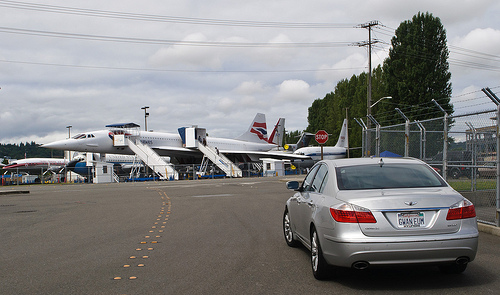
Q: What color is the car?
A: Silver.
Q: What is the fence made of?
A: Metal.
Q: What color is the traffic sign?
A: Red and white.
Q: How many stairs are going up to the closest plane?
A: Two.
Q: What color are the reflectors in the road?
A: Orange.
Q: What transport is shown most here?
A: Airplanes.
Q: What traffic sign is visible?
A: STOP sign.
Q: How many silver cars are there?
A: One.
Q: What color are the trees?
A: Green.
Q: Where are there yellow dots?
A: The road.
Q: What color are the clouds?
A: White.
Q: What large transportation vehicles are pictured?
A: Airplanes.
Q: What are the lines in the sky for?
A: Power lines.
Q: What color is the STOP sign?
A: Red.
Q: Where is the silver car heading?
A: Towards the airport.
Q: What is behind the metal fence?
A: An aircraft.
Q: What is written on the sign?
A: Stop.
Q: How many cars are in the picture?
A: 1.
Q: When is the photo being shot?
A: Daytime.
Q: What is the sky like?
A: Cloudy.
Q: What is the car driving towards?
A: A plane.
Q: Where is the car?
A: On the road.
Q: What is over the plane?
A: Powerlines.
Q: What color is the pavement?
A: Black.